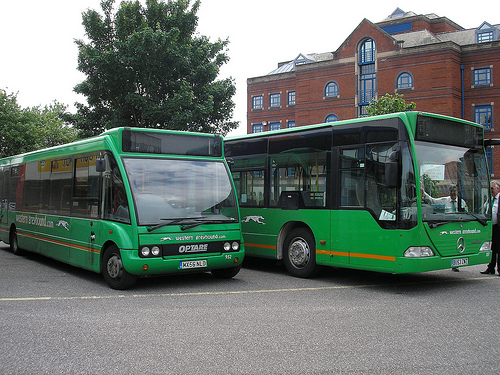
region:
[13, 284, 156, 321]
large white line on ground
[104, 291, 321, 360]
rough edges on gray surface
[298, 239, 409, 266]
orange line on green bus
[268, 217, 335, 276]
large wheel in bus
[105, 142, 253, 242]
wide clear window in front of bus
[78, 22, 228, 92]
large green tree with leaves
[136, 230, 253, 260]
white lights at front of bus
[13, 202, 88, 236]
white symbol on side of green bus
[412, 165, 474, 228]
man standing at door of bus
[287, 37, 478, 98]
tall red buildings with curved windows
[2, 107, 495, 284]
Two large green buses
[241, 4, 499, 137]
Brick building in background.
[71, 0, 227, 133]
A large green tree in background.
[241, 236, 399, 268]
Orange decorative stripe on bus.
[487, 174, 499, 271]
A man in a shirt and tie.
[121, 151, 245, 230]
Large glass windshield of a bus.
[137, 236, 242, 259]
Headlights on a green bus.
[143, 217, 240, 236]
Windshield wipers on a green bus.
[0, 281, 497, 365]
Gray pavement in a parkinglot.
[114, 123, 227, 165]
Route display board on front of bus.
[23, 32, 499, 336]
Picture of two green buses.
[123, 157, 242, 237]
Front windshield of bus on left.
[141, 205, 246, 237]
Windshield wipers of bus on left.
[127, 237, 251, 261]
Headlights of bus on left.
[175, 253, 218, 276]
White license tag of bus on left.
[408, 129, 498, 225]
Front windshield of bus on right.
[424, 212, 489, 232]
Windshield wipers of bus on right.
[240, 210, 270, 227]
White greyhound dog emblem of bus on right.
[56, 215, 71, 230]
White greyhound dog emblem of bus on left.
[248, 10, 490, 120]
A red brick building.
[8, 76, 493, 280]
There are two busses in the photo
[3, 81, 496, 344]
The photo was taken during the day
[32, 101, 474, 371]
The two busses are green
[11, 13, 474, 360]
There are trees in the background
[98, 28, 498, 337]
There is a building in the background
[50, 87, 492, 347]
The busses are turned off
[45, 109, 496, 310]
The busses are faced in the same direction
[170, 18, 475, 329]
The building in the background is brown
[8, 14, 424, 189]
The sky is gray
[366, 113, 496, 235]
There are two men near the bus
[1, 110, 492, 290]
a pair of green buses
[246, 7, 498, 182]
large brick building behind buses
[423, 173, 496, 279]
two men standing near bus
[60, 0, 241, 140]
tall tree behind bus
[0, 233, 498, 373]
concrete parking lot with buses parked on it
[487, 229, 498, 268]
black pants on man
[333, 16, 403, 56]
pointed top of building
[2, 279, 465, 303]
white line on parking lot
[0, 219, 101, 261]
orange stripe on bus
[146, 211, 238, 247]
windshield wipers on bus